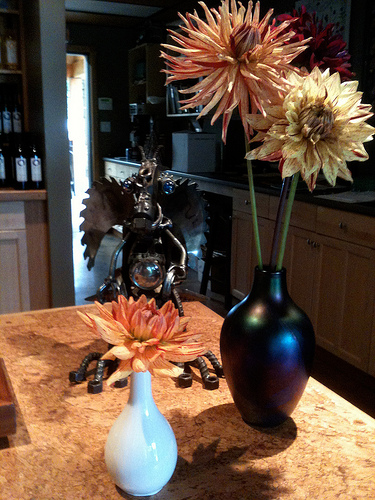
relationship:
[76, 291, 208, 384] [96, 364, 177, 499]
flower in vase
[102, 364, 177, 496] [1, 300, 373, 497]
flower vase on table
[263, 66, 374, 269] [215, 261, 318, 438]
flower in vase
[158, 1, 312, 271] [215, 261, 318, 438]
flower in vase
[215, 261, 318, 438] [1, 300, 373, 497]
vase on table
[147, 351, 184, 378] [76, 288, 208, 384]
petal on flower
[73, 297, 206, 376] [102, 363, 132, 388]
petal on flower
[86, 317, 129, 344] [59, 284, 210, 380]
petal on flower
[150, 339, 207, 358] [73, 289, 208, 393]
petal on flower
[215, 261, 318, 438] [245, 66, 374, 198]
vase with flower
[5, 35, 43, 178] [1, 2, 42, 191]
bottles on shelves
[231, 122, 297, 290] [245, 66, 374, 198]
stems on flower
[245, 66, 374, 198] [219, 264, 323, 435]
flower in vase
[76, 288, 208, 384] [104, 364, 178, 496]
flower in flower vase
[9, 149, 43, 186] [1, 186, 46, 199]
bottles on table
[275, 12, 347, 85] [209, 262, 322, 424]
flower in vase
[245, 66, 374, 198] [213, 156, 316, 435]
flower in vase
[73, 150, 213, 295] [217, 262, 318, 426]
statue behind vase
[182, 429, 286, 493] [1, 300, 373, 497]
shadow on table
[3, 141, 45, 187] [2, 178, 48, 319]
bottles on shelf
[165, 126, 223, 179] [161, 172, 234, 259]
box on counter